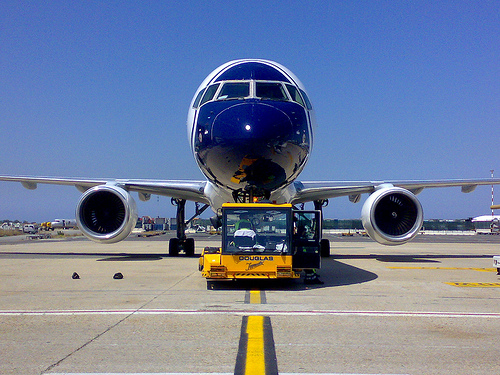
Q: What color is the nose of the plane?
A: Blue.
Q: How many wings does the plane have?
A: Two.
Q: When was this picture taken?
A: Daytime.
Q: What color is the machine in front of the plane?
A: Yellow.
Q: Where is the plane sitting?
A: Tarmac.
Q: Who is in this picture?
A: No one.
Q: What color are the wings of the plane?
A: White.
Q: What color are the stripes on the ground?
A: Black and yellow.